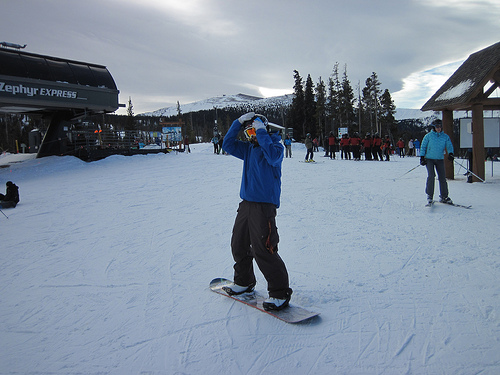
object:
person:
[219, 110, 295, 311]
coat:
[218, 117, 287, 209]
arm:
[253, 128, 285, 168]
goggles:
[242, 126, 258, 139]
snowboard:
[204, 276, 319, 326]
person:
[418, 119, 458, 206]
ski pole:
[453, 158, 489, 186]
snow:
[1, 77, 498, 375]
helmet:
[243, 113, 269, 129]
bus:
[0, 41, 125, 120]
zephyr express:
[0, 82, 79, 101]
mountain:
[136, 92, 297, 116]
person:
[326, 130, 339, 160]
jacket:
[340, 137, 351, 147]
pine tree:
[289, 68, 307, 142]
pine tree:
[303, 72, 317, 141]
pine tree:
[360, 70, 384, 133]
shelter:
[419, 41, 500, 183]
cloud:
[0, 0, 500, 114]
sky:
[0, 0, 500, 129]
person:
[0, 179, 20, 209]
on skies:
[440, 197, 475, 210]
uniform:
[326, 131, 340, 160]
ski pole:
[391, 159, 427, 182]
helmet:
[431, 118, 445, 129]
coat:
[419, 129, 456, 161]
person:
[347, 132, 361, 162]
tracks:
[222, 300, 243, 331]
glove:
[248, 116, 270, 132]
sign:
[160, 126, 184, 142]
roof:
[418, 40, 500, 111]